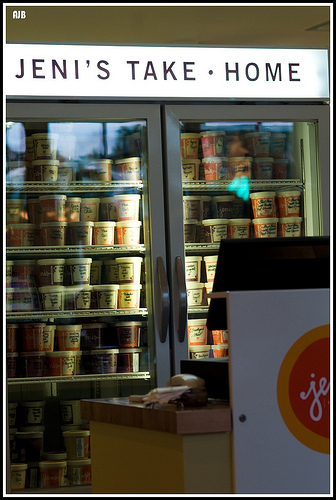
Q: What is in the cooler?
A: Ice cream.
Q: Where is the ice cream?
A: In the cooler.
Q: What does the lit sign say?
A: Jeni's Take Home.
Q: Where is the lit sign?
A: Above the cooler.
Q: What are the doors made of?
A: Glass.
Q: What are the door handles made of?
A: Metal.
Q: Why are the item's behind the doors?
A: To keep them cool.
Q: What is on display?
A: Ice cream.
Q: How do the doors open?
A: With the handles.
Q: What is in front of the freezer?
A: A white cashier's stand.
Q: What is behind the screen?
A: A glass case containing the ice cream.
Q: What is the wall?
A: This is a store refrigerator.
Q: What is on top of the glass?
A: A white sign on the front of the refrigerator.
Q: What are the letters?
A: The letters are black.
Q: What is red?
A: Sign.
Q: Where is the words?
A: Above the case.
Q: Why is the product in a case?
A: To keep frozen.